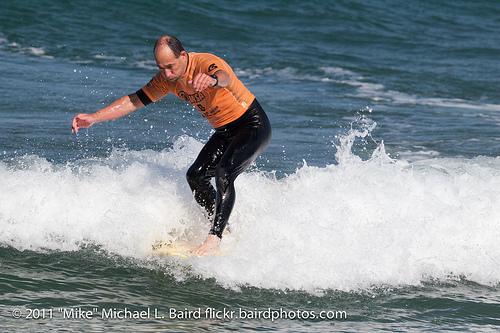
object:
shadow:
[126, 84, 218, 116]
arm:
[92, 73, 169, 124]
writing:
[9, 303, 351, 322]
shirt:
[135, 51, 257, 129]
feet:
[197, 234, 224, 257]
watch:
[209, 74, 219, 87]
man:
[68, 31, 276, 256]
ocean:
[0, 0, 500, 333]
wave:
[0, 99, 500, 299]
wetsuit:
[132, 50, 275, 243]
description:
[9, 306, 349, 321]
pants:
[183, 98, 274, 240]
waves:
[380, 217, 436, 248]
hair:
[152, 33, 187, 60]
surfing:
[127, 151, 300, 271]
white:
[382, 239, 420, 262]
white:
[83, 209, 132, 230]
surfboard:
[148, 217, 238, 260]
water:
[7, 134, 497, 333]